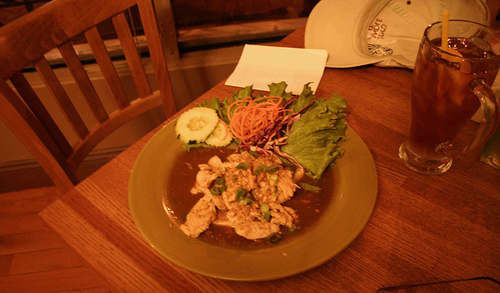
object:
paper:
[224, 42, 328, 96]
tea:
[407, 36, 495, 158]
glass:
[396, 19, 497, 175]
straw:
[436, 10, 452, 68]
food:
[179, 82, 348, 238]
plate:
[127, 102, 378, 282]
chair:
[3, 0, 194, 191]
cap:
[303, 0, 492, 70]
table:
[341, 72, 398, 131]